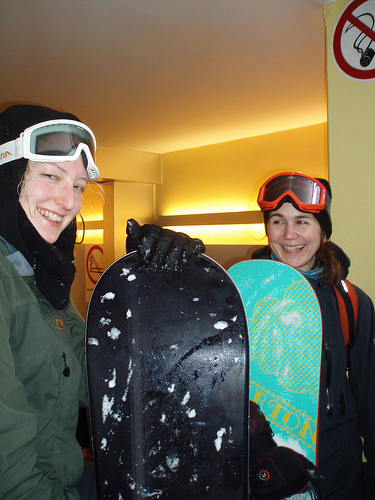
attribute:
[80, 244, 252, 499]
snowboard — black, snowy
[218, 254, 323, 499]
snowboard — green, blue, aqua, yellow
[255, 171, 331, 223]
goggles — orange, skiing, red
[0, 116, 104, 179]
goggles — white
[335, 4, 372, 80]
sign — no smoking, red, white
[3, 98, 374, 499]
women — standing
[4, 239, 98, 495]
jacket — green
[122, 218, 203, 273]
gloves — black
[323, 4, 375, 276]
wall — lit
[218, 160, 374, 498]
woman — smiling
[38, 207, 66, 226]
teeth — present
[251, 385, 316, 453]
writing — yellow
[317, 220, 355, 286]
hair — brown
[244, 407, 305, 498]
glove — purple